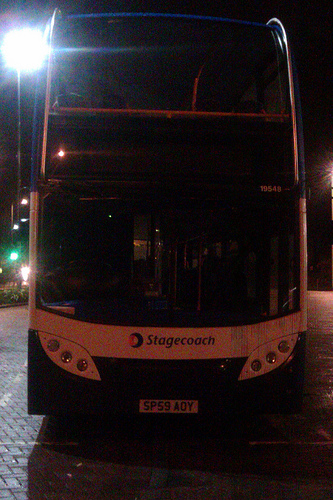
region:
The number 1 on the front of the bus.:
[257, 184, 264, 192]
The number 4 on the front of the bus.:
[267, 181, 278, 191]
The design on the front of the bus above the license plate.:
[125, 333, 144, 346]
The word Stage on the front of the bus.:
[145, 332, 181, 347]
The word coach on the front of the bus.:
[180, 332, 218, 346]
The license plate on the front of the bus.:
[137, 399, 198, 410]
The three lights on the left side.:
[38, 331, 93, 376]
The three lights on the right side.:
[240, 341, 292, 374]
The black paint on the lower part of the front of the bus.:
[23, 332, 312, 416]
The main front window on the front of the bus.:
[47, 180, 297, 316]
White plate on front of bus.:
[132, 393, 212, 434]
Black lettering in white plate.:
[133, 392, 223, 437]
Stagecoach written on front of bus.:
[122, 328, 259, 374]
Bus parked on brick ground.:
[14, 372, 266, 473]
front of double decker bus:
[24, 16, 308, 363]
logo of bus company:
[121, 327, 220, 357]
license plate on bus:
[135, 392, 204, 421]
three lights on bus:
[239, 336, 294, 384]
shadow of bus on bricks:
[20, 418, 83, 457]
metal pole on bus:
[283, 41, 300, 147]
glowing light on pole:
[1, 15, 52, 91]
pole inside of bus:
[181, 234, 212, 307]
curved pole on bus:
[262, 12, 292, 38]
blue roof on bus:
[128, 7, 257, 25]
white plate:
[133, 391, 245, 442]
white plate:
[127, 352, 216, 441]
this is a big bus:
[2, 3, 325, 426]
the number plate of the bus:
[135, 388, 200, 417]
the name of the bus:
[128, 320, 223, 355]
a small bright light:
[56, 145, 67, 160]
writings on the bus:
[127, 396, 202, 421]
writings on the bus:
[142, 331, 217, 353]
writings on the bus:
[246, 183, 289, 199]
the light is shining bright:
[0, 19, 46, 86]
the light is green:
[1, 244, 21, 265]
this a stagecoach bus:
[19, 0, 314, 429]